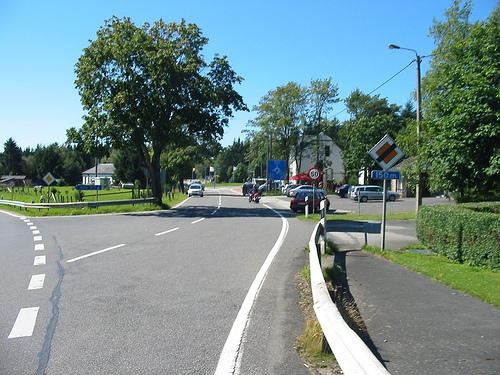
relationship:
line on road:
[13, 219, 49, 372] [0, 206, 285, 373]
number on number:
[308, 165, 322, 180] [307, 167, 321, 181]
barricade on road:
[302, 212, 394, 374] [0, 206, 285, 373]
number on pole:
[307, 167, 321, 181] [310, 182, 320, 211]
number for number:
[307, 167, 321, 181] [307, 167, 321, 181]